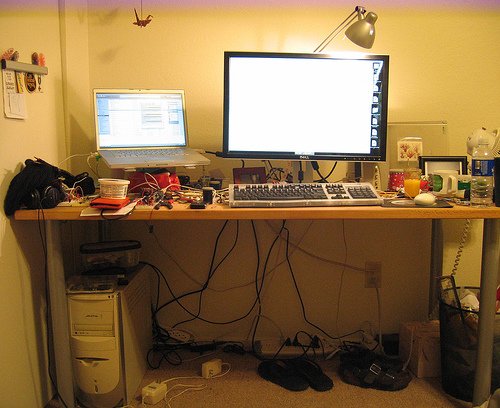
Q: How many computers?
A: Two.